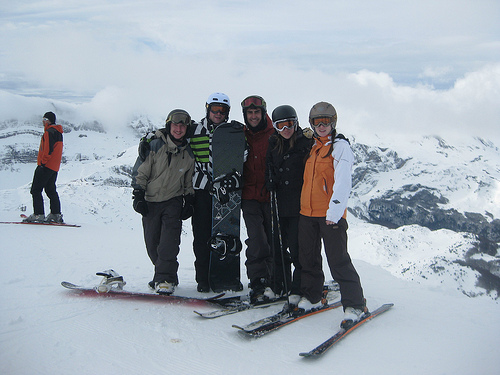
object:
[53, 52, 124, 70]
clouds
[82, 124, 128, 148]
sky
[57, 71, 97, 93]
sky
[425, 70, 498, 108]
clouds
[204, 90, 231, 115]
helmet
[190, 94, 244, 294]
man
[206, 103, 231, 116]
goggles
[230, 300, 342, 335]
ski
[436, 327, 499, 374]
ground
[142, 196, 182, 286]
pants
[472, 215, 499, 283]
mountains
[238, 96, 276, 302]
person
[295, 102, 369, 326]
person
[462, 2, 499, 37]
sky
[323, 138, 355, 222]
arm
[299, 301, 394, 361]
ski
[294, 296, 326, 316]
boot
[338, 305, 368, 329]
boot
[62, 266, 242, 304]
snowboard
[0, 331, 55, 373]
snow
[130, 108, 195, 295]
man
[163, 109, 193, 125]
goggles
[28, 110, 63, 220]
man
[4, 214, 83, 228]
skis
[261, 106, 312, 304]
girl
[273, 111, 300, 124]
hair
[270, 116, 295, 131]
goggles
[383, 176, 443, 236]
mountain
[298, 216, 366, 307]
pants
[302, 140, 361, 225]
jacket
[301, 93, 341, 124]
helmet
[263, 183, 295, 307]
poles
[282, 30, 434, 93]
area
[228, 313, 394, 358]
skis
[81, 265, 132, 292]
boot mount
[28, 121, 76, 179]
jacket